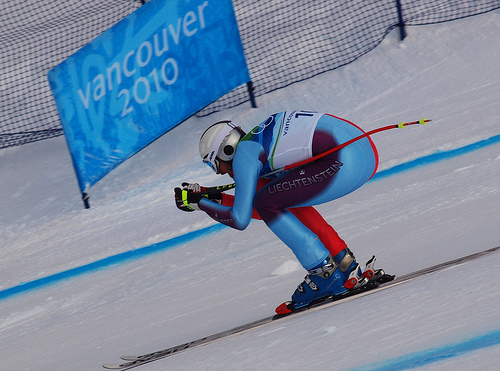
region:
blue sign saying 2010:
[109, 61, 215, 116]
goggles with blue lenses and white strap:
[199, 121, 239, 171]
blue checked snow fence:
[242, 10, 378, 70]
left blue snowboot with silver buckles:
[283, 260, 373, 307]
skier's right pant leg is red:
[309, 212, 381, 273]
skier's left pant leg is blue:
[266, 221, 327, 268]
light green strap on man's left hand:
[166, 183, 217, 219]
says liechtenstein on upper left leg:
[260, 149, 360, 206]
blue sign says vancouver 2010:
[54, 0, 263, 196]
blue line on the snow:
[367, 323, 497, 369]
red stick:
[332, 80, 497, 184]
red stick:
[257, 131, 415, 238]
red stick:
[274, 92, 379, 212]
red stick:
[291, 118, 428, 168]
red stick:
[338, 22, 463, 162]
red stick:
[207, 120, 451, 304]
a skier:
[175, 100, 413, 337]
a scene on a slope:
[9, 6, 481, 368]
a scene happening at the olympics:
[5, 2, 465, 363]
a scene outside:
[11, 6, 496, 365]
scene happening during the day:
[5, 0, 479, 366]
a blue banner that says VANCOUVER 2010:
[51, 7, 262, 204]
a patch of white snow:
[2, 26, 497, 369]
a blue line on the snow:
[0, 131, 499, 296]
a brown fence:
[0, 1, 498, 163]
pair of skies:
[72, 242, 497, 369]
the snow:
[290, 355, 317, 362]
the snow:
[298, 321, 328, 359]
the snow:
[338, 323, 383, 363]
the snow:
[319, 325, 364, 365]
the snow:
[377, 315, 415, 359]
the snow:
[302, 360, 337, 368]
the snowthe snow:
[354, 310, 399, 357]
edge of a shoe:
[286, 277, 335, 317]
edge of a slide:
[235, 322, 262, 337]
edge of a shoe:
[308, 286, 359, 313]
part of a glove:
[176, 187, 200, 224]